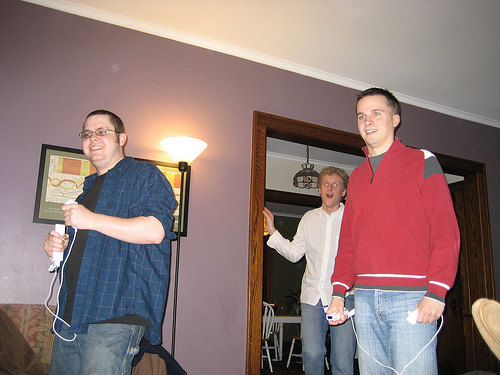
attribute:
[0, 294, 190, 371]
sofa — comfy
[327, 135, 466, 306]
shirt — red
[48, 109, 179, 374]
guy — smiling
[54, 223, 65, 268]
controller — white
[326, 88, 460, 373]
guy — suprised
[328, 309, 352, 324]
controller — white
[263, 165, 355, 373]
man — stunned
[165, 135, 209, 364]
lamp — on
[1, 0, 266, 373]
wall — lavender, plum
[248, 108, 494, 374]
archway — brown, wooden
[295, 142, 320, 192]
lamp — white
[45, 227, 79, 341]
cord — white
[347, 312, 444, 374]
cord — white